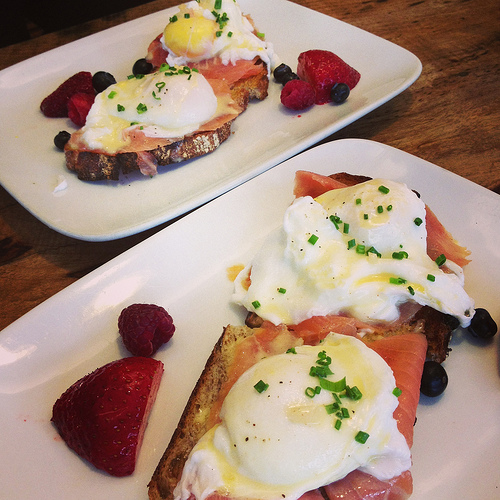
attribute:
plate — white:
[0, 0, 423, 242]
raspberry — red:
[120, 304, 176, 357]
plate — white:
[1, 137, 499, 499]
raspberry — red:
[281, 79, 315, 108]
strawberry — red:
[53, 355, 164, 478]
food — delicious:
[40, 0, 362, 185]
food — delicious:
[53, 170, 500, 499]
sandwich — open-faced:
[149, 170, 474, 498]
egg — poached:
[175, 331, 414, 499]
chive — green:
[255, 379, 269, 394]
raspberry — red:
[68, 94, 95, 126]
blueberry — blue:
[53, 131, 72, 147]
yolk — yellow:
[166, 11, 219, 56]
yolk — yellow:
[107, 117, 132, 154]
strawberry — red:
[40, 72, 95, 117]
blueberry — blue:
[132, 59, 154, 80]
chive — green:
[156, 81, 166, 91]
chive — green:
[308, 234, 320, 244]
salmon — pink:
[266, 169, 474, 327]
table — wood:
[0, 1, 500, 332]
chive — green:
[212, 10, 223, 18]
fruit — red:
[53, 302, 176, 476]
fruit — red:
[282, 50, 361, 110]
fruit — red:
[40, 71, 96, 126]